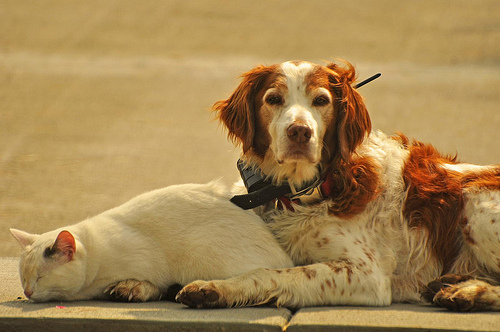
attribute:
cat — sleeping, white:
[3, 182, 216, 291]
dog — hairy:
[225, 30, 471, 314]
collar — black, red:
[230, 160, 349, 237]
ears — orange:
[219, 55, 380, 190]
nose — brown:
[284, 121, 310, 147]